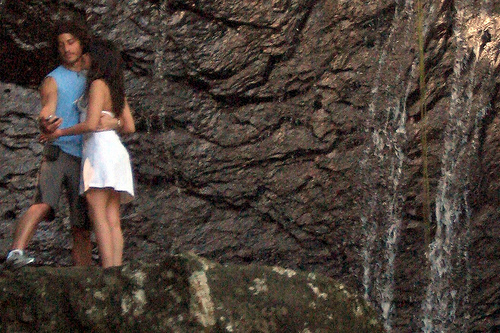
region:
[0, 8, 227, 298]
a couple on a rock path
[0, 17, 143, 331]
one of two people interested in a selfie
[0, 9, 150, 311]
young man in blue shirt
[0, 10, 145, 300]
young lady happy being held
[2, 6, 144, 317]
a hug for romance and for safety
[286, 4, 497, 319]
water falling from rocks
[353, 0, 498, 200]
a glimmer of sunlight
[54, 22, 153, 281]
girl with long hair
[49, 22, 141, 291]
a girl dressed to be noticed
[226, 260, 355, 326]
growth on rocks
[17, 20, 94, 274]
Man with dark skin and hair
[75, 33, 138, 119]
Woman with dark hair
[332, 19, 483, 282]
Small waterfall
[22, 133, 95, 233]
Black and grey shorts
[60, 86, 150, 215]
Short white dress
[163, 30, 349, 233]
Dark rock wall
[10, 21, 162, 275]
Man and woman taking picture of themselves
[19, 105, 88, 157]
Cellphone in mans hand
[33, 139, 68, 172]
Black cell phone case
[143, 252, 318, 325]
Dark grey and white rock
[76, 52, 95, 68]
the girl kisses a guy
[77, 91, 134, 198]
the girl wears a white dress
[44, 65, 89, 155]
the man has a blue shirt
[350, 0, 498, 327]
a waterfall in the photo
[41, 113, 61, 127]
they are taking a selfie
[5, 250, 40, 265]
the man wears sneakers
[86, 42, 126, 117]
the girl has long hair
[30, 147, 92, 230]
the man has gray shorts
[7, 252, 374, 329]
the rock has moss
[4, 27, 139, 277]
the couple is hugging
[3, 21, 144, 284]
man and woman embrace on the edge of a cliff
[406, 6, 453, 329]
water flows down the side of the rocks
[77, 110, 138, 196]
woman is wearing a white dress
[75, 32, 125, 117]
woman has long black hair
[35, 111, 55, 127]
hand is holding phone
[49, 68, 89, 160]
a blue sleeveless t-shirt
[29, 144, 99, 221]
a gray pair of shorts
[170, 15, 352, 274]
rough textured side of a rock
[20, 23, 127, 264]
man and woman prepare to take a selfie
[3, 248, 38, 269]
foot of man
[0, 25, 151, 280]
a young couple posing for a photo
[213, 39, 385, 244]
a black rock wall surrounds a couple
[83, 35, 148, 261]
a woman is wearing a white sundress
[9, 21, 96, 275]
a guy wearing a blue shirt takes selfie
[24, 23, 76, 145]
a man takes a selfie with his phone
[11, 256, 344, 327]
a large black and white stone supports a kissing couple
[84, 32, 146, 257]
a young woman whispers in her lover's ear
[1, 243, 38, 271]
a gray shoe covers the foot of a man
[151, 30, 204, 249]
clear water drips down the slick black rocks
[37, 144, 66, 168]
a cell phone holder is clipped to the shorts of a man